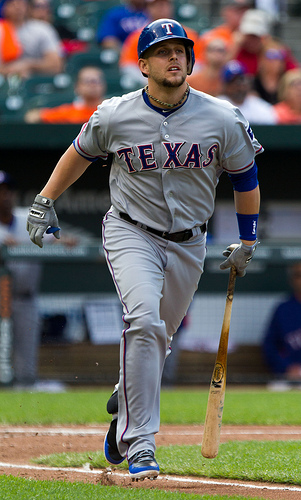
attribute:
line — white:
[1, 453, 100, 485]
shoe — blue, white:
[126, 451, 162, 478]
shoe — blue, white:
[103, 416, 125, 465]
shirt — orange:
[39, 103, 95, 121]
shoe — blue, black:
[103, 417, 128, 465]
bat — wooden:
[195, 240, 259, 464]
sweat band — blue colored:
[234, 209, 260, 241]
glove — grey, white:
[25, 194, 60, 247]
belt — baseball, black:
[117, 208, 208, 245]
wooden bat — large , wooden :
[202, 252, 235, 458]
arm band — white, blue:
[231, 207, 263, 244]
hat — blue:
[136, 18, 195, 66]